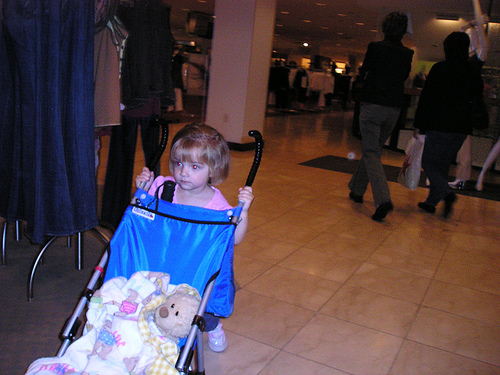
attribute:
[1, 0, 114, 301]
rack — metal, clothes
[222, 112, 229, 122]
outlet — white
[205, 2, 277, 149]
pillar — white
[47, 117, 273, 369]
stroller — metal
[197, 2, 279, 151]
beam — black, white, support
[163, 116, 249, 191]
hair — brown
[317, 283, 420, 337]
tile — white, stone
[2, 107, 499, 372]
floor — tile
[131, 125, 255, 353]
girl — little, young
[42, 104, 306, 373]
stroller — blue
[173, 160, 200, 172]
eyes — red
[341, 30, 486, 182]
people — walking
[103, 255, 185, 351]
animal — stuffed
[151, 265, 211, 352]
bear — brown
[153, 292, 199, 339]
teddy bear — brown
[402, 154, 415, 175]
star — red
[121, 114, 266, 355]
girl — young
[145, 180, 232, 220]
shirt — pink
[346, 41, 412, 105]
jacket — black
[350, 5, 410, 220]
person — walking